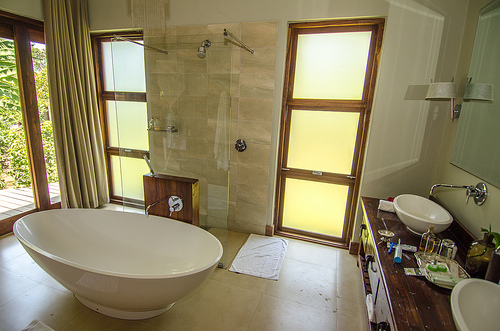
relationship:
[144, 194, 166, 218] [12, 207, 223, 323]
faucet next to bathtub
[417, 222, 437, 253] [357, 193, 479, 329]
bottle on top of counter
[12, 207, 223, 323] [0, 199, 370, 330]
bathtub on top of floor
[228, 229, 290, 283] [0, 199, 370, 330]
towel on floor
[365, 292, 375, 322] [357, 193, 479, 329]
rag under counter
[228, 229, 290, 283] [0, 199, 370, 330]
towel laying on floor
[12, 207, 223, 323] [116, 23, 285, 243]
bathtub in front of shower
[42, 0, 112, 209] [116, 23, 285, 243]
curtain behind shower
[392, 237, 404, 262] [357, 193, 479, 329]
toothbrush on top of counter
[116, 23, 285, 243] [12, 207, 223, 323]
shower behind bathtub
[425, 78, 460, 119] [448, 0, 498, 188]
lamp next to mirror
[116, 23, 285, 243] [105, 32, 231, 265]
shower has glass walls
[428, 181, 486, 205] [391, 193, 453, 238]
faucet above sink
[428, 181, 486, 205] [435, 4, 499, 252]
faucet on wall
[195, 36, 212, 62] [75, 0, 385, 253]
shower head on wall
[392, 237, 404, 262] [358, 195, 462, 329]
toothbrush sitting on counter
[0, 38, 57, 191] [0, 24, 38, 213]
bush outside window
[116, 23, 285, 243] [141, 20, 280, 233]
shower has wall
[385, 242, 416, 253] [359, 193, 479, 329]
toothpaste sitting on counter top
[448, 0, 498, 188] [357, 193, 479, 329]
mirror above counter